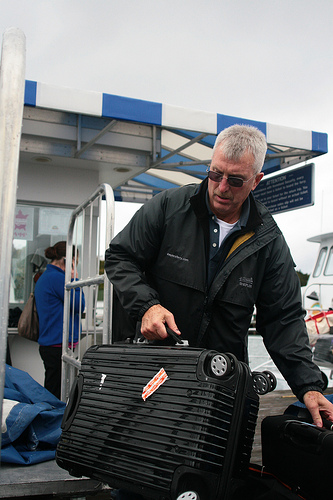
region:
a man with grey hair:
[105, 104, 331, 365]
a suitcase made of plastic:
[43, 319, 310, 496]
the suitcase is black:
[45, 311, 270, 479]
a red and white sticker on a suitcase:
[115, 350, 250, 494]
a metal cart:
[6, 183, 125, 493]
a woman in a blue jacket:
[30, 227, 107, 405]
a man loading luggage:
[75, 103, 312, 484]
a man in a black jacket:
[96, 107, 315, 339]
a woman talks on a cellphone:
[26, 225, 111, 401]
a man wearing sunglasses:
[142, 108, 316, 310]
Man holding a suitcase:
[60, 105, 330, 497]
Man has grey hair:
[86, 112, 331, 447]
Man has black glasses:
[91, 122, 332, 426]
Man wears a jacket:
[70, 120, 332, 432]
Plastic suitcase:
[44, 321, 277, 498]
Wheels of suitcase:
[204, 343, 287, 399]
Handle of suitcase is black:
[131, 315, 189, 350]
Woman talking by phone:
[26, 228, 89, 404]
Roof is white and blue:
[21, 75, 324, 152]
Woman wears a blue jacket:
[24, 229, 96, 424]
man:
[102, 100, 329, 394]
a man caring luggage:
[94, 88, 309, 496]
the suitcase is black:
[54, 314, 286, 499]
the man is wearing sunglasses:
[79, 105, 324, 381]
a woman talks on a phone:
[31, 220, 97, 379]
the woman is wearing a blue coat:
[31, 228, 120, 381]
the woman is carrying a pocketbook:
[20, 235, 111, 399]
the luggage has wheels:
[61, 316, 277, 476]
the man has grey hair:
[83, 104, 311, 235]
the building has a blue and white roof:
[27, 64, 330, 214]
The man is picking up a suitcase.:
[51, 108, 328, 488]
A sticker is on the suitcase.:
[128, 354, 183, 420]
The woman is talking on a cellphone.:
[14, 229, 78, 407]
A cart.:
[0, 179, 122, 494]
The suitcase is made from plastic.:
[46, 338, 282, 493]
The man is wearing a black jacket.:
[100, 118, 326, 413]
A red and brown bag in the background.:
[298, 296, 331, 346]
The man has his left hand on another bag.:
[258, 333, 326, 457]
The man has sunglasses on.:
[197, 116, 264, 218]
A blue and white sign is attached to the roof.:
[235, 118, 327, 216]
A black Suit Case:
[90, 333, 263, 491]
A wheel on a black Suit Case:
[197, 348, 258, 430]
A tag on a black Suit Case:
[124, 363, 180, 406]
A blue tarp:
[7, 358, 62, 472]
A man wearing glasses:
[188, 135, 283, 219]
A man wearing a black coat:
[161, 130, 318, 390]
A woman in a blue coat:
[42, 236, 85, 362]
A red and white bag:
[310, 298, 331, 348]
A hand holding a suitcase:
[121, 296, 204, 401]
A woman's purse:
[21, 260, 44, 358]